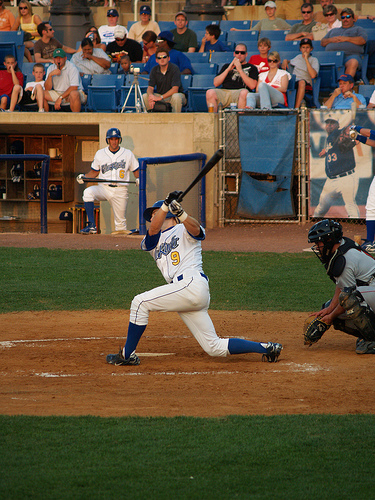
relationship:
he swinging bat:
[107, 198, 286, 371] [162, 145, 231, 221]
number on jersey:
[97, 156, 139, 185] [139, 217, 208, 276]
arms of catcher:
[302, 283, 344, 342] [276, 181, 374, 362]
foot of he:
[105, 347, 141, 365] [106, 190, 283, 367]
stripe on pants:
[132, 275, 194, 325] [125, 272, 230, 351]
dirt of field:
[2, 215, 372, 273] [1, 229, 372, 388]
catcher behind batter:
[300, 215, 374, 354] [114, 196, 280, 364]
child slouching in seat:
[9, 64, 48, 111] [18, 59, 57, 110]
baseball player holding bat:
[72, 130, 138, 232] [66, 173, 132, 193]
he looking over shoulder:
[106, 190, 283, 367] [133, 234, 173, 247]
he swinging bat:
[106, 190, 283, 367] [167, 113, 240, 220]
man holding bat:
[77, 126, 139, 233] [81, 174, 133, 183]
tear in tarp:
[230, 168, 285, 185] [231, 109, 303, 216]